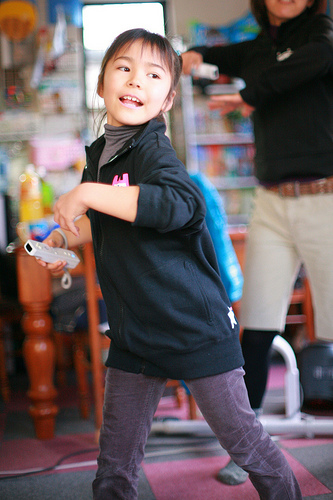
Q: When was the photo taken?
A: Day time.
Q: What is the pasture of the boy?
A: Standing.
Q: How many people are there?
A: 2.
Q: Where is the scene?
A: Department store.